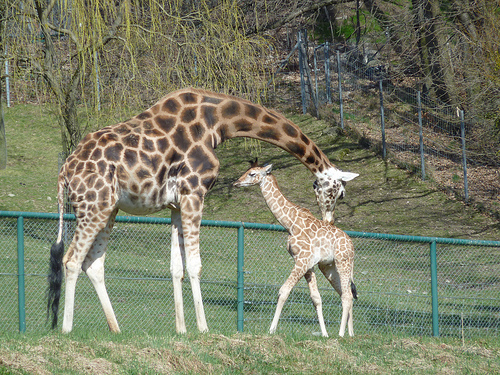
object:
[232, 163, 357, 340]
giraffe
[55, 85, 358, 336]
giraffe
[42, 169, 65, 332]
tail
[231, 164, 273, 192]
head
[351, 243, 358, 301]
tail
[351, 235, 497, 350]
fence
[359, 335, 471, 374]
field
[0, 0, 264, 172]
tree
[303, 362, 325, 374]
grass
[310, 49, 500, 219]
fence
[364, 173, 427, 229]
hillside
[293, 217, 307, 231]
spots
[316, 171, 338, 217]
face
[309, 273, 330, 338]
legs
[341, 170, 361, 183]
ear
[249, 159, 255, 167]
horns